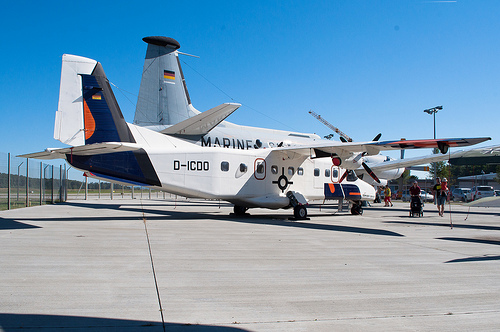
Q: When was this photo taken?
A: Daytime.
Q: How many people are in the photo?
A: 5.